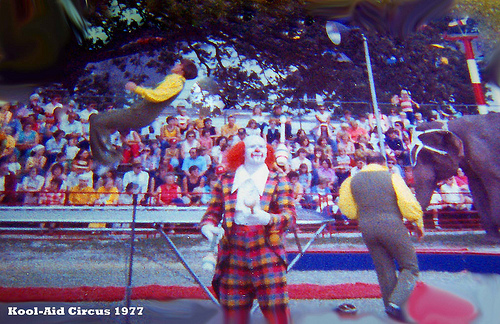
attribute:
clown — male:
[192, 126, 316, 323]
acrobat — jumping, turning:
[75, 46, 204, 174]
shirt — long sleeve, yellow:
[328, 161, 431, 229]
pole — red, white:
[437, 6, 496, 117]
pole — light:
[354, 29, 394, 158]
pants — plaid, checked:
[215, 222, 295, 324]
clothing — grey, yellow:
[334, 161, 430, 321]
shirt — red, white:
[35, 187, 70, 206]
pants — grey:
[355, 213, 428, 305]